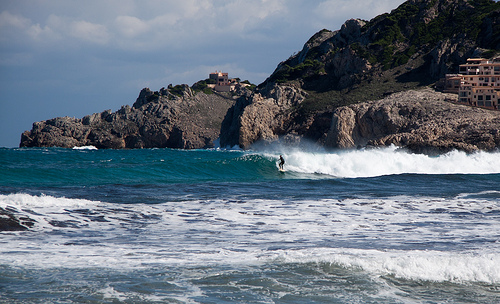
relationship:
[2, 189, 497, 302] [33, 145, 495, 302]
foam on water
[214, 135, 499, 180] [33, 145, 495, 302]
foam on water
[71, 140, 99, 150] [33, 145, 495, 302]
foam on water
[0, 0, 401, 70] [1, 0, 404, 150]
clouds in sky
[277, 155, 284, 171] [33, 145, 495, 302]
man in water